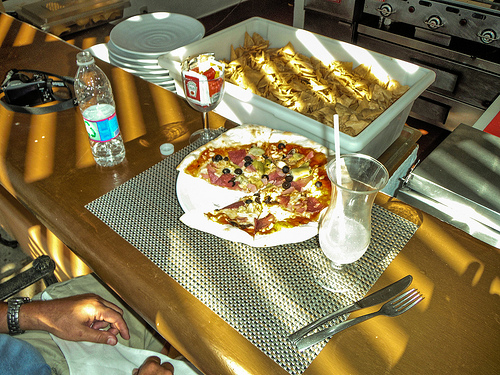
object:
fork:
[355, 289, 434, 340]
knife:
[283, 274, 411, 317]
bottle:
[72, 47, 128, 170]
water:
[94, 149, 128, 167]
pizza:
[175, 126, 346, 259]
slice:
[179, 189, 263, 247]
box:
[164, 16, 430, 153]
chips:
[272, 57, 338, 103]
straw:
[331, 114, 347, 183]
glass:
[318, 205, 366, 294]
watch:
[7, 295, 32, 337]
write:
[32, 297, 62, 335]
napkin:
[52, 331, 200, 373]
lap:
[13, 333, 68, 371]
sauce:
[179, 62, 226, 112]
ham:
[246, 176, 271, 194]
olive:
[281, 164, 291, 174]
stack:
[103, 10, 211, 97]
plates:
[108, 14, 206, 65]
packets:
[182, 67, 209, 108]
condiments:
[189, 55, 225, 82]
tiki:
[323, 154, 378, 261]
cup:
[310, 149, 389, 296]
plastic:
[72, 53, 115, 116]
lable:
[69, 101, 135, 143]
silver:
[297, 318, 336, 353]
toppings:
[228, 152, 311, 191]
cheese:
[265, 197, 301, 227]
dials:
[374, 2, 498, 44]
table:
[0, 36, 499, 373]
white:
[178, 185, 206, 210]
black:
[12, 77, 47, 102]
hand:
[37, 289, 131, 348]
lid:
[156, 138, 177, 159]